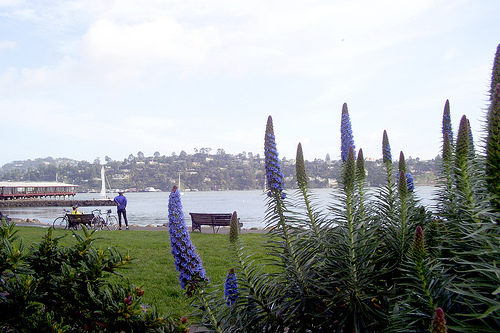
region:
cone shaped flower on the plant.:
[157, 180, 227, 318]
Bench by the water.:
[188, 207, 243, 240]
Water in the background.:
[1, 182, 461, 227]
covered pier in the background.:
[1, 172, 78, 203]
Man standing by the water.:
[111, 187, 135, 227]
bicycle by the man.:
[87, 205, 118, 235]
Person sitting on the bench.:
[65, 199, 84, 221]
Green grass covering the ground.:
[7, 221, 289, 326]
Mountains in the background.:
[0, 149, 480, 192]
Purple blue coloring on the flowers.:
[254, 112, 296, 202]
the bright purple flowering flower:
[167, 184, 205, 292]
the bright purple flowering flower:
[226, 266, 236, 306]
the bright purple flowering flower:
[262, 114, 283, 195]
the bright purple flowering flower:
[339, 100, 355, 167]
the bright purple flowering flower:
[441, 100, 453, 157]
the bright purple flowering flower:
[399, 169, 415, 195]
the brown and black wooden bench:
[65, 213, 99, 228]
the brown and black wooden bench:
[188, 208, 243, 230]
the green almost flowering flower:
[295, 141, 310, 185]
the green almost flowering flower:
[341, 146, 356, 193]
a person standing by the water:
[112, 190, 129, 228]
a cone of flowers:
[166, 184, 206, 288]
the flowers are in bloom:
[167, 73, 497, 290]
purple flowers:
[169, 230, 199, 271]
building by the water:
[0, 180, 75, 197]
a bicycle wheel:
[50, 214, 70, 229]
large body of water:
[53, 188, 433, 220]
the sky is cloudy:
[7, 7, 483, 150]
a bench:
[189, 212, 242, 229]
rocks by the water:
[9, 215, 41, 224]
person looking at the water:
[111, 189, 132, 230]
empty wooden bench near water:
[189, 208, 244, 233]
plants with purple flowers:
[165, 77, 499, 317]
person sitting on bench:
[64, 205, 85, 214]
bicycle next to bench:
[92, 207, 117, 232]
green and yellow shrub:
[0, 208, 182, 332]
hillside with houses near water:
[25, 145, 338, 190]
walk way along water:
[12, 218, 276, 237]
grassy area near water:
[10, 222, 282, 321]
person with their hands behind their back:
[113, 189, 130, 229]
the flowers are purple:
[139, 178, 217, 297]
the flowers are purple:
[156, 175, 206, 284]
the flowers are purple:
[248, 118, 299, 210]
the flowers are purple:
[141, 180, 226, 292]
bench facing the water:
[182, 200, 244, 237]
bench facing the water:
[186, 188, 246, 237]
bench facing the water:
[182, 190, 246, 239]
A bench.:
[188, 211, 245, 233]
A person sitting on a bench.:
[63, 203, 97, 228]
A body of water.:
[7, 189, 498, 225]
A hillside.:
[6, 147, 488, 195]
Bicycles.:
[47, 203, 119, 236]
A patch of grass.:
[9, 218, 305, 330]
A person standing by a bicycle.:
[107, 183, 132, 235]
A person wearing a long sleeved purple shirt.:
[112, 188, 130, 232]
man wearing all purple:
[107, 186, 132, 231]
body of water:
[10, 176, 476, 231]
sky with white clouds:
[5, 5, 495, 150]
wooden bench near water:
[190, 211, 235, 226]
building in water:
[5, 172, 75, 197]